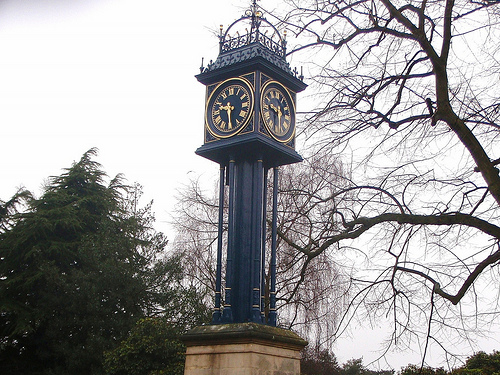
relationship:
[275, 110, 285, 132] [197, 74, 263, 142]
hand part of clock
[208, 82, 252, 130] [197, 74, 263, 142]
face part of clock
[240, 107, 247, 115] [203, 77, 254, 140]
numerals on clock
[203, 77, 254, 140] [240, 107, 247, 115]
clock has numerals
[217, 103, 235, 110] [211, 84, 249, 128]
hour hand on face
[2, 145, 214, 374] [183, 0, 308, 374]
tree next to clock tower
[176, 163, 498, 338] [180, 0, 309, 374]
branches behind clock tower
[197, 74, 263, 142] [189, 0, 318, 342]
clock side of tower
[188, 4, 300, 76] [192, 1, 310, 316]
top of clock tower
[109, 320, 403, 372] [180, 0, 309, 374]
part of a clock tower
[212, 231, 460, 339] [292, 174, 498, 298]
part of a branch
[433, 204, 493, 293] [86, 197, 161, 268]
part of a tree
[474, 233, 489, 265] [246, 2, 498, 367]
part of a tree